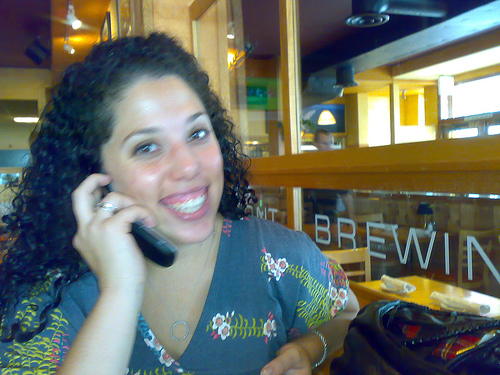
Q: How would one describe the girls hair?
A: Long curly black.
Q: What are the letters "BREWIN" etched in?
A: Glass divider.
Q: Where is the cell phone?
A: Girl's right hand.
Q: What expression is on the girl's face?
A: Smile.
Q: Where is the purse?
A: To the girl's left.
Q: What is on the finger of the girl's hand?
A: Ring.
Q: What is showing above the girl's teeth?
A: The girl's gums.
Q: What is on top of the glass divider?
A: Wooden beam.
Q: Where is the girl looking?
A: At the camera.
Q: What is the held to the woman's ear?
A: Cell phone.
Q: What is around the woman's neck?
A: Necklace.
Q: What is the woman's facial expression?
A: Smiling.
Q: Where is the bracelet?
A: Woman's wrist.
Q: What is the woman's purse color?
A: Black.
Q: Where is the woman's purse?
A: On table.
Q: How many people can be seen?
A: Two.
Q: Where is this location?
A: Restaurant.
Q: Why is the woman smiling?
A: Get her picture taken.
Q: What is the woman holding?
A: Cell.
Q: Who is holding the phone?
A: A woman.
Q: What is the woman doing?
A: Smiling.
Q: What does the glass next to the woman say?
A: Brewin.